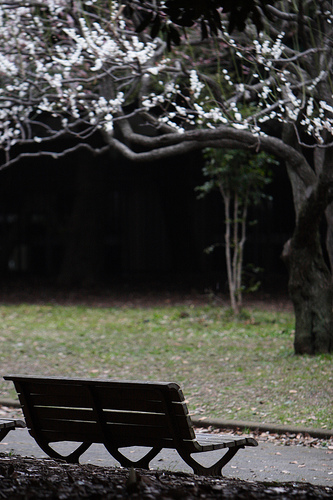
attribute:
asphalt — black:
[244, 446, 308, 480]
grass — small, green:
[0, 296, 329, 428]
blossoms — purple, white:
[183, 68, 208, 108]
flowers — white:
[55, 20, 160, 70]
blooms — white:
[0, 0, 332, 150]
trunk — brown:
[277, 164, 331, 354]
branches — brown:
[91, 113, 310, 175]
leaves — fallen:
[198, 421, 332, 450]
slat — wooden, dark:
[0, 371, 182, 398]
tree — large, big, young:
[0, 3, 332, 354]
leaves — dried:
[188, 333, 274, 352]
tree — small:
[191, 138, 293, 314]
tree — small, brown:
[192, 145, 280, 322]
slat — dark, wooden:
[14, 406, 192, 426]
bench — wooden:
[1, 371, 260, 486]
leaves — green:
[192, 147, 278, 209]